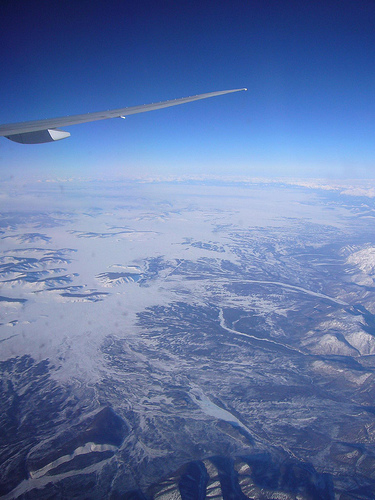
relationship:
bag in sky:
[284, 169, 299, 184] [3, 13, 374, 161]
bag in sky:
[12, 126, 80, 156] [2, 4, 363, 498]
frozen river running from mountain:
[216, 306, 303, 353] [82, 334, 348, 499]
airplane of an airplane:
[0, 88, 248, 144] [4, 72, 250, 156]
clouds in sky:
[267, 175, 346, 196] [34, 12, 344, 167]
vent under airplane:
[4, 126, 71, 145] [0, 88, 248, 144]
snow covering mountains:
[30, 288, 86, 339] [13, 253, 113, 315]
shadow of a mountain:
[333, 440, 368, 462] [21, 239, 374, 490]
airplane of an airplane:
[0, 88, 248, 144] [2, 67, 252, 161]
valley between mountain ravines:
[218, 458, 243, 496] [185, 437, 270, 498]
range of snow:
[1, 171, 374, 498] [1, 162, 373, 499]